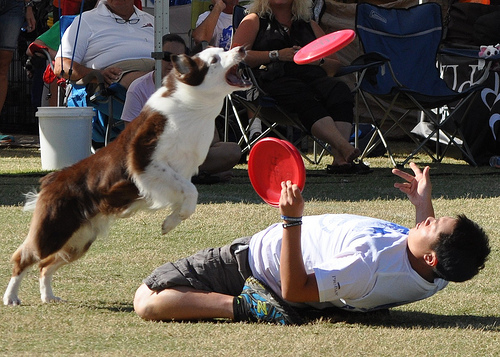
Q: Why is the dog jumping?
A: Catching frisbee.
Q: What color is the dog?
A: Brown and white.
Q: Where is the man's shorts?
A: Body.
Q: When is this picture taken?
A: During day.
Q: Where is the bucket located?
A: Next to man.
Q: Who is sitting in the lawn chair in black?
A: Woman.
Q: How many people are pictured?
A: 5.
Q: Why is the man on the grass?
A: Playing.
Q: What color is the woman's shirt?
A: Black.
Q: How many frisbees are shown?
A: Two.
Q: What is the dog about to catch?
A: A frisbee.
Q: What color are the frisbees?
A: Red.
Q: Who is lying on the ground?
A: A man.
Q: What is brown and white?
A: A dog.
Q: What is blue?
A: Lawn chair.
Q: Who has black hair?
A: Man on ground.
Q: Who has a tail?
A: Dog.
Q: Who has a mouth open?
A: The dog.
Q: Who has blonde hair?
A: Woman in black.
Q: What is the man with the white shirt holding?
A: A frisbee.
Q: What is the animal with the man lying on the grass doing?
A: Leaping to catch a frisbee.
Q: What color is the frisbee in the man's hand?
A: Red.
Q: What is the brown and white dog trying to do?
A: Catch a frisbee.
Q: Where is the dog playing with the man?
A: On the grass.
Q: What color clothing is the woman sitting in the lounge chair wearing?
A: Black.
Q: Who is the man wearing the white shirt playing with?
A: The dog.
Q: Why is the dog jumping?
A: To catch a frisbee.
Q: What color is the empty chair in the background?
A: Blue.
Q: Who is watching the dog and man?
A: Lady sitting.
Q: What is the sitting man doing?
A: Watching man and dog.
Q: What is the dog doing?
A: Jumping.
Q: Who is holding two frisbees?
A: The man.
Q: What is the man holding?
A: Two red frisbees.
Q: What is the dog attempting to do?
A: Catch a frisbee.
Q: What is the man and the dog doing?
A: Showing off their frisbee skills.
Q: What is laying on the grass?
A: Man in shorts and a white t-shirt.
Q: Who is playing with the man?
A: Brown and white dog.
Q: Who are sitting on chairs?
A: Spectators.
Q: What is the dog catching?
A: Frisbee.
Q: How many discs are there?
A: 2.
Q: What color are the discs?
A: Red.